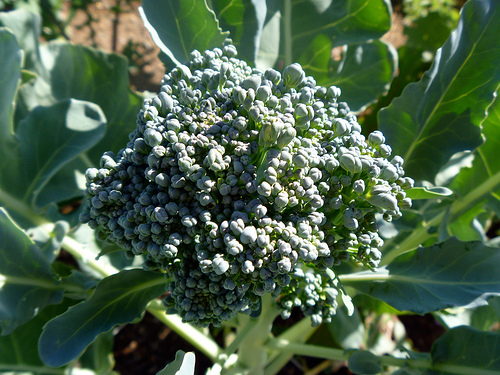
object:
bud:
[262, 121, 282, 144]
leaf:
[373, 1, 497, 190]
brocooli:
[75, 41, 423, 328]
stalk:
[204, 320, 249, 374]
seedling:
[310, 100, 329, 114]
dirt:
[112, 315, 210, 375]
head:
[75, 44, 414, 332]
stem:
[337, 271, 382, 285]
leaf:
[343, 230, 497, 322]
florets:
[279, 61, 306, 89]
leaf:
[342, 348, 387, 375]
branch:
[349, 237, 498, 315]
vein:
[441, 73, 496, 106]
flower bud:
[364, 192, 399, 211]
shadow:
[119, 38, 164, 95]